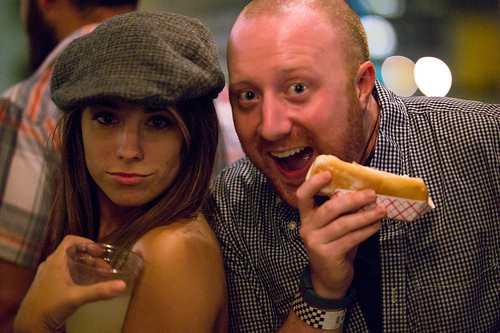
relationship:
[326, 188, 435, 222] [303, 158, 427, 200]
basket holding hot dog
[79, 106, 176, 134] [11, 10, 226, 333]
eyes of woman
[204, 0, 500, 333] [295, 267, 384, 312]
man wearing watch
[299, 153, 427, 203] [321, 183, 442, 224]
hotdog in basket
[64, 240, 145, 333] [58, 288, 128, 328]
beverage full of a beverage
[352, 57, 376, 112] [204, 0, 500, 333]
ear of man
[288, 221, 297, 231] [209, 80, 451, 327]
button on shirt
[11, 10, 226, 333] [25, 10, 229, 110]
woman wearing a hat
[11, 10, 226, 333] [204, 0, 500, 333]
woman standing next to a man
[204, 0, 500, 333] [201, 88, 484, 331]
man wearing a dressing shirt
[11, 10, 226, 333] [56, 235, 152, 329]
woman holding beverage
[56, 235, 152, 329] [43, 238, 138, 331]
beverage in hand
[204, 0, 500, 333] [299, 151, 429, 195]
man holding hotdog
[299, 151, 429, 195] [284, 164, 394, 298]
hotdog in hand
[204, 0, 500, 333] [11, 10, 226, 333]
man leaning against woman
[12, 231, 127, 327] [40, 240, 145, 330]
hand holding beverage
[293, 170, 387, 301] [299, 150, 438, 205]
hand holding hotdog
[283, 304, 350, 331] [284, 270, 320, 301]
band of a watch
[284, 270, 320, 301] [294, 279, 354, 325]
watch around a wrist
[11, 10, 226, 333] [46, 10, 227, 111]
woman wearing a hat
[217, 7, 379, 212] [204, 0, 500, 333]
head of a man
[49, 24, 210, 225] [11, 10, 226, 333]
head of a woman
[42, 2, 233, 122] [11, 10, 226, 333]
hat on woman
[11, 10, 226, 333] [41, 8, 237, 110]
woman wearing hat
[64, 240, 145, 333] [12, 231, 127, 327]
beverage in hand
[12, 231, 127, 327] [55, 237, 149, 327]
hand holding cup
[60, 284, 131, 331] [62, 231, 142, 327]
liquid in cup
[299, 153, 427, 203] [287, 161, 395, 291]
hotdog in mans hand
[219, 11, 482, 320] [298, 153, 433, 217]
man holding food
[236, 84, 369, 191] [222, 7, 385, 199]
hair on man's face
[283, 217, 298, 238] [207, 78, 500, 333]
button on shirt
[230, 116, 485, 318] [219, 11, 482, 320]
shirt on man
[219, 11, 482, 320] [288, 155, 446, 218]
man holding sandwich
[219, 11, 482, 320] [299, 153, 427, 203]
man holding hotdog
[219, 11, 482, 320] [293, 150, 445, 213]
man holding sandwich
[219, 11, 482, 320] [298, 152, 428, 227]
man holding sandwich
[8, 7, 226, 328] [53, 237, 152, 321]
girl holding cup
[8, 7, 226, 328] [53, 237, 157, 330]
girl holding cup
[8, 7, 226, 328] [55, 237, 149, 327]
girl holding cup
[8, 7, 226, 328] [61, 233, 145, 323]
girl holding cup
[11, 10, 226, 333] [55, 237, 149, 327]
woman holding cup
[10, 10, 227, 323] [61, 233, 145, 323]
woman holding cup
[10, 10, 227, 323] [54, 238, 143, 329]
woman holding cup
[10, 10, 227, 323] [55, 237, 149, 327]
woman holding cup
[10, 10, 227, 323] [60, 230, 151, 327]
woman holding cup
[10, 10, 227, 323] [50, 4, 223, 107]
woman wearing a hat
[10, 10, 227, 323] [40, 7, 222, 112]
woman wearing a hat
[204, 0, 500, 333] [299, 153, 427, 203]
man holding hotdog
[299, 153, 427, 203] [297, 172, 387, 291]
hotdog in hand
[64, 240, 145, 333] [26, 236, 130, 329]
beverage inside of hand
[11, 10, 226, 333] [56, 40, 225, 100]
woman wearing hat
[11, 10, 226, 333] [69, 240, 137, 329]
woman holding glass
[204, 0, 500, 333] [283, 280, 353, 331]
man wearing bracelet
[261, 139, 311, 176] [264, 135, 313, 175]
teeth are in mouth